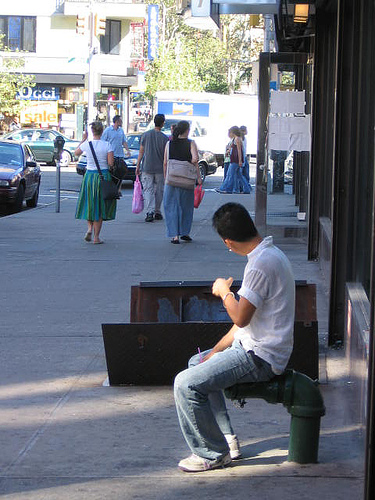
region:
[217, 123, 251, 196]
woman wearing long blue maxi skirt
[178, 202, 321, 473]
man sitting on green pipe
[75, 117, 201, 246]
women wearing long, modest skirts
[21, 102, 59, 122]
sale banner in store window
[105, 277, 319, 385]
open doors to cellar entry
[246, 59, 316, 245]
open door with flyers taped to glass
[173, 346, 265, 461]
The jeans the man sitting down is wearing.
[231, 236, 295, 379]
The white shirt the man sitting down is wearing.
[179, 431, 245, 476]
The sneakers the man sitting down is wearing.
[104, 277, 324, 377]
The open metal doors.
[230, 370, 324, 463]
The green pipe the man is sitting on.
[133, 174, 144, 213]
The pink bag the man is holding.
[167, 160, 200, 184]
The tan bag the woman is carrying.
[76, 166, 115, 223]
The green skirt the woman is wearing.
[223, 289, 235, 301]
The bracelet on the man's wrist that is sitting down.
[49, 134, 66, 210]
The parking meter on the sidewalk.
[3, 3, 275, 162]
white buildings, trees and vehicles on one side of street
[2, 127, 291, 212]
cars on top of gray paved street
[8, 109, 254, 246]
pedestrians with bags walking in different directions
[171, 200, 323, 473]
man sitting on curved green pipe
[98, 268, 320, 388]
dark panels open showing worn inner surface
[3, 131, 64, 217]
car parked at curb ny parking meter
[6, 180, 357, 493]
wide gray sidewalk covered with stains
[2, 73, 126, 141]
storefront with signs covering windows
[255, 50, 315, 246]
open door with black frame with signs attached to window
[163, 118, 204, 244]
woman with large shoulder bag and wide pants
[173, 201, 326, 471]
Man sitting on a fire hydrant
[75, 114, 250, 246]
People wallking on the sidewalk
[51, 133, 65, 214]
Parking meter near the curb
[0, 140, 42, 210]
Car parked at the curb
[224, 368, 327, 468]
Green fire hydrant on the pavement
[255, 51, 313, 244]
Opened glass door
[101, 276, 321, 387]
Open doors in pavement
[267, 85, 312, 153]
Signs taped to the door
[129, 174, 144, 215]
Bag in man's hand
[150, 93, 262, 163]
Budget truck on the road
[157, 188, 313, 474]
man sitting on tube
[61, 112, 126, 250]
lady walking on side walk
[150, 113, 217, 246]
lady walking on side walk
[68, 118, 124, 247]
lady wearing a blue and green skirt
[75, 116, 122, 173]
lady wearing a white shirt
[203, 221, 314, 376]
man wearing a white shirt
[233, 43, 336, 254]
glass shop door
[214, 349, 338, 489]
green tube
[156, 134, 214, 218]
lady holding a beige bag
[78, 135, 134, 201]
lady holding black bag